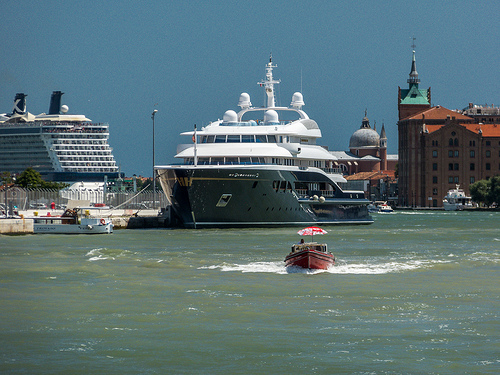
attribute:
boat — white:
[170, 67, 411, 224]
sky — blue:
[2, 2, 497, 150]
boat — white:
[436, 180, 486, 211]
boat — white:
[155, 50, 375, 225]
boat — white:
[25, 205, 114, 236]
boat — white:
[370, 196, 393, 216]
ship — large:
[149, 59, 369, 230]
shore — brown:
[8, 195, 161, 237]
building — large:
[398, 32, 498, 205]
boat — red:
[277, 242, 354, 266]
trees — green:
[473, 172, 498, 210]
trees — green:
[18, 164, 48, 189]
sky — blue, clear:
[5, 7, 496, 169]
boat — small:
[276, 219, 341, 283]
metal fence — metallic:
[10, 179, 174, 219]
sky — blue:
[107, 29, 214, 113]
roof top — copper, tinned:
[389, 37, 434, 113]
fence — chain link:
[3, 186, 170, 209]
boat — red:
[276, 226, 337, 281]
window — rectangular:
[241, 134, 253, 142]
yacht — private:
[151, 52, 373, 228]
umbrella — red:
[298, 224, 326, 239]